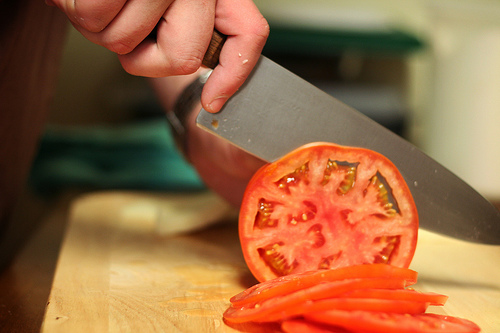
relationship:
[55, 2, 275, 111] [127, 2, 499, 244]
fingers grasping knife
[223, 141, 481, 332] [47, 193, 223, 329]
tomato on board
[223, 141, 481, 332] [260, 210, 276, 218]
tomato has seed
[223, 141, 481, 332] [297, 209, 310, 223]
tomato has seed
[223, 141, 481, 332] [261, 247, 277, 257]
tomato has seed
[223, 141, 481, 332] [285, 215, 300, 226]
tomato has seed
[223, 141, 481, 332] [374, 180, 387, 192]
tomato has seed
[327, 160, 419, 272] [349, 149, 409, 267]
seeds showing in flesh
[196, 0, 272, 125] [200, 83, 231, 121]
finger has fingernail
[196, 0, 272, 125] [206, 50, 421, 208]
finger on metal background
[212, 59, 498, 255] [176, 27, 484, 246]
blade on knife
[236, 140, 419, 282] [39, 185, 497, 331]
tomato on counter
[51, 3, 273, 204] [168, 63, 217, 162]
person wearing band